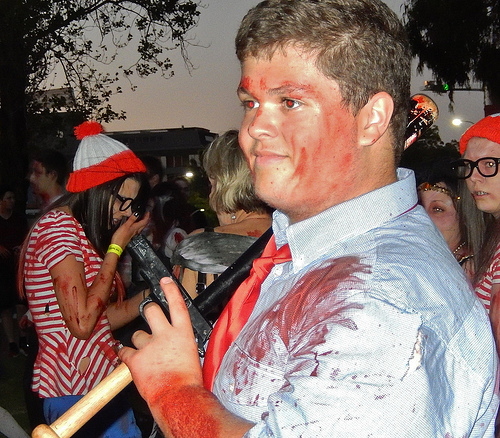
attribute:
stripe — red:
[38, 350, 78, 384]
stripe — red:
[42, 367, 66, 393]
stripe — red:
[40, 383, 52, 399]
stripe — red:
[35, 316, 61, 328]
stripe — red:
[28, 287, 58, 301]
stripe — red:
[24, 276, 54, 287]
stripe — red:
[471, 286, 493, 302]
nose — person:
[247, 111, 277, 141]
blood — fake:
[279, 275, 332, 321]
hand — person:
[114, 272, 207, 399]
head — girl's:
[73, 169, 135, 246]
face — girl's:
[103, 178, 137, 229]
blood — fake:
[293, 147, 311, 182]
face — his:
[232, 50, 354, 212]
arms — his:
[129, 339, 248, 435]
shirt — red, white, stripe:
[28, 202, 131, 392]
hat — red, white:
[61, 117, 146, 193]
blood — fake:
[56, 276, 78, 296]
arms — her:
[39, 245, 143, 332]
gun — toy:
[128, 237, 202, 362]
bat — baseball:
[58, 103, 438, 322]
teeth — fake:
[472, 188, 486, 201]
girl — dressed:
[31, 122, 151, 426]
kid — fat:
[197, 0, 448, 436]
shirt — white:
[199, 186, 491, 433]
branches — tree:
[42, 3, 179, 82]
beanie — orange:
[451, 109, 497, 142]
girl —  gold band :
[25, 109, 157, 394]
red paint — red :
[224, 62, 370, 212]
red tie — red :
[185, 235, 302, 389]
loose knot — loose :
[243, 235, 292, 283]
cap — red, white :
[61, 117, 149, 190]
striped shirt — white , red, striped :
[12, 205, 142, 395]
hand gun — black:
[120, 230, 223, 369]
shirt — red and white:
[200, 160, 499, 435]